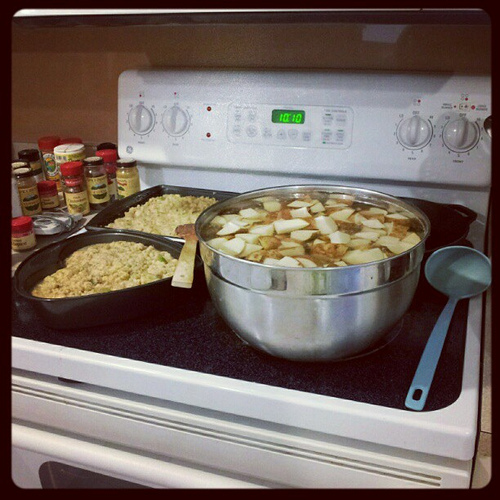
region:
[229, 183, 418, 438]
a bowl of potatoes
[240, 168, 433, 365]
a bowl of water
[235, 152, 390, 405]
a bowl of water and potatoes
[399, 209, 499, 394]
a spoon on teh stove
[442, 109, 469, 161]
a knob on stove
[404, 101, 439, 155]
a knob on stove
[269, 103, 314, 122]
green letters on stove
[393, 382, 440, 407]
small hole in cooking spoon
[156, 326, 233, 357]
grainy surface on stove top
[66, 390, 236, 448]
lines on stove's door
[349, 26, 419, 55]
white vent on wall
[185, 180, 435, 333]
large silver pot on stove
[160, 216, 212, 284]
wooden spoon in food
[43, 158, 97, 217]
green herbs in container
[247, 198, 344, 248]
cut up potato in pot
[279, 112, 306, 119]
the time is green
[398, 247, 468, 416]
the ladle is blue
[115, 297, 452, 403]
the stovetop is black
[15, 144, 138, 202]
spices on the counter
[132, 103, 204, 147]
the knobs are white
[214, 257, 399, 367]
the pot is silver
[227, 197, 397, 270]
potatoes in the pot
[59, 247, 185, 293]
casserole in the dish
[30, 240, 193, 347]
dish on the stove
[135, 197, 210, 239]
the casserole is tan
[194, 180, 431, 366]
Sliced potatoes water in a silver bowl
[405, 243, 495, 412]
Blue ladle on the stovetop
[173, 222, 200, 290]
Wooden spoon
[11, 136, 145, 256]
Spices on the counter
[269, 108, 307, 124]
Digital clock showing 10:10 on the stove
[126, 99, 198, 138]
Two control knobs on the stove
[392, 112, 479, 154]
Two control knobs on right of the stove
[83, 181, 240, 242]
Square pan of food on the stovetop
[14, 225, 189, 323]
Food in a heart-shaped pan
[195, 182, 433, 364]
Silver bowl filled with potatoes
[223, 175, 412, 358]
a pot of potato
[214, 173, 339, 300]
potato and water in pot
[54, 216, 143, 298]
a pan of food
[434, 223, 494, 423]
a spoon on the stove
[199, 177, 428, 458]
as ilver bowl on stove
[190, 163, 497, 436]
a bowl on stove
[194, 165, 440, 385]
a large bowl on stove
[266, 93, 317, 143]
a clock on stove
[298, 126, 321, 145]
button on the stove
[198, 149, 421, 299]
Potatoes cut in cube shapes.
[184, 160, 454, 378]
Potatoes soaking in bowl of water.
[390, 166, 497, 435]
Blue plastic ladle laying on stovetop.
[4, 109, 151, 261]
Assortment of seasonings on countertop.